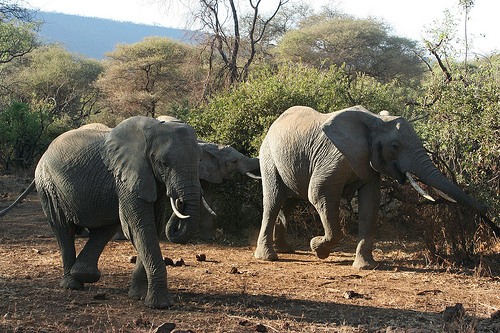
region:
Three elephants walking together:
[21, 93, 492, 315]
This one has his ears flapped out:
[298, 98, 447, 210]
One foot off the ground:
[241, 207, 391, 281]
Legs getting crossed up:
[53, 243, 116, 297]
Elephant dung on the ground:
[168, 246, 251, 278]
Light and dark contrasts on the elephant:
[301, 103, 376, 207]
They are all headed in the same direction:
[19, 72, 496, 318]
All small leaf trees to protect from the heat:
[1, 6, 496, 101]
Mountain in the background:
[14, 0, 276, 75]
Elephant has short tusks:
[134, 172, 242, 239]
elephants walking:
[20, 94, 470, 311]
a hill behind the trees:
[20, 0, 252, 67]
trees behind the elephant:
[1, 1, 498, 249]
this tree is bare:
[188, 1, 288, 96]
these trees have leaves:
[9, 10, 498, 187]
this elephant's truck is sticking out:
[246, 101, 498, 262]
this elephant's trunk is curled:
[157, 179, 222, 246]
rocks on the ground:
[5, 230, 477, 331]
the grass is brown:
[6, 183, 496, 328]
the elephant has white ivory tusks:
[160, 196, 223, 221]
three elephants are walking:
[34, 85, 482, 332]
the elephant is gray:
[23, 95, 232, 311]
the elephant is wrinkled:
[18, 95, 173, 325]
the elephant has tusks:
[158, 175, 231, 235]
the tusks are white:
[148, 183, 269, 255]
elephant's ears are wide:
[304, 84, 464, 229]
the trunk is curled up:
[137, 152, 244, 285]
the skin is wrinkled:
[43, 113, 200, 316]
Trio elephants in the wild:
[0, 106, 497, 308]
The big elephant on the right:
[257, 104, 499, 269]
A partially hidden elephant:
[199, 124, 260, 244]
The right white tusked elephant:
[0, 114, 215, 307]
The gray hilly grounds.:
[0, 2, 227, 60]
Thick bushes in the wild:
[0, 0, 497, 253]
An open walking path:
[0, 184, 498, 331]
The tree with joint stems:
[199, 0, 289, 80]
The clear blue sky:
[0, 0, 498, 54]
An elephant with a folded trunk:
[1, 114, 218, 309]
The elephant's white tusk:
[164, 197, 184, 218]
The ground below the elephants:
[205, 272, 319, 317]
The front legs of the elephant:
[117, 213, 167, 300]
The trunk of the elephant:
[428, 166, 493, 208]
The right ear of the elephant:
[324, 105, 367, 172]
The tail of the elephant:
[4, 176, 34, 211]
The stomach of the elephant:
[78, 199, 116, 231]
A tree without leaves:
[188, 1, 264, 83]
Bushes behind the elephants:
[244, 71, 362, 106]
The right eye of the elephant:
[389, 135, 406, 150]